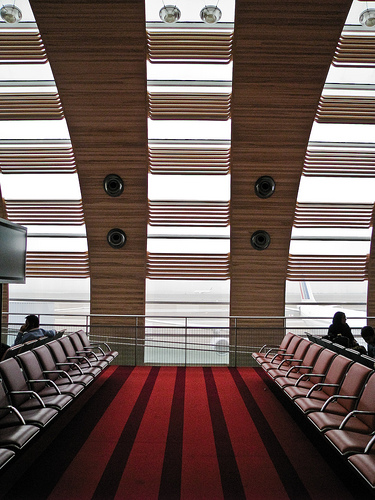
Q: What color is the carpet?
A: Red and black.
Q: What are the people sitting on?
A: Chairs.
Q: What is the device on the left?
A: A television screen.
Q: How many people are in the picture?
A: Three.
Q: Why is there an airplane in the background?
A: The picture is of an airport.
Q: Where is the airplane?
A: Outside of the room.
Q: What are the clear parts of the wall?
A: Windows.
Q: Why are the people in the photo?
A: Waiting for their flight.